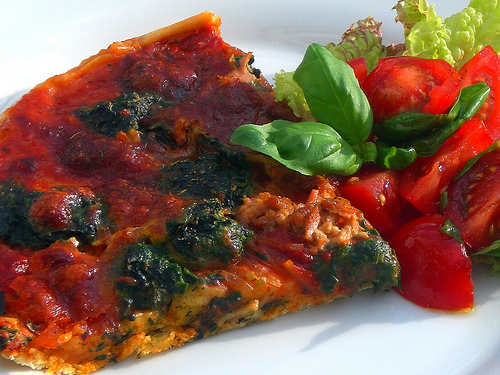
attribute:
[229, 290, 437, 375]
plate — white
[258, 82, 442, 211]
leaves — green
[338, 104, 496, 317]
tomatoes — red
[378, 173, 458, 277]
tomatoes — red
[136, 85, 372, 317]
spinach — green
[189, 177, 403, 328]
sauce — green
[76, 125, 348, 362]
spices — small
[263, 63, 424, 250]
leaves — green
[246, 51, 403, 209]
leaves — green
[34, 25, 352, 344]
pizza — sliced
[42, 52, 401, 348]
pizza — sliced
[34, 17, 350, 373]
pizza — sliced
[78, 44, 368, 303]
pizza — sliced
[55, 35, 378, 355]
pizza — sliced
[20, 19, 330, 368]
pizza — sliced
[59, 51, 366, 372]
pizza — sliced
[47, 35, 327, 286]
pizza — sliced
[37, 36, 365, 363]
pizza — sliced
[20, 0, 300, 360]
pizza — sliced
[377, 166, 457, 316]
tomato — red